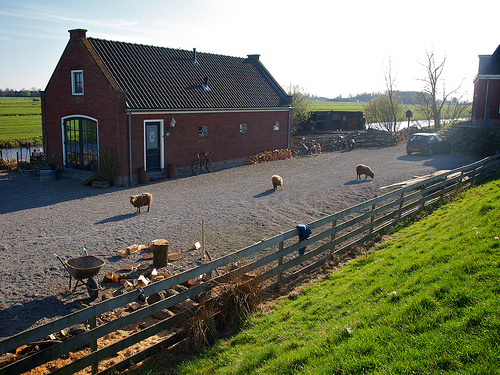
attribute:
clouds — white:
[225, 12, 472, 98]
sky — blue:
[7, 0, 155, 44]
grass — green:
[179, 178, 498, 373]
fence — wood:
[42, 190, 499, 374]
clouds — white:
[298, 13, 430, 75]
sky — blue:
[91, 4, 496, 98]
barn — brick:
[37, 37, 302, 180]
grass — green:
[339, 239, 499, 374]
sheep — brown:
[256, 166, 294, 194]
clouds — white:
[193, 16, 391, 76]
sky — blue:
[2, 2, 493, 104]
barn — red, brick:
[29, 14, 312, 200]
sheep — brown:
[126, 190, 154, 214]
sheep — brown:
[269, 172, 286, 190]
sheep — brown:
[354, 162, 374, 181]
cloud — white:
[0, 12, 190, 33]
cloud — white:
[2, 68, 50, 91]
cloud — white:
[121, 3, 497, 108]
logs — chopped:
[149, 235, 174, 269]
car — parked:
[404, 131, 451, 156]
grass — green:
[126, 174, 498, 374]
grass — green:
[0, 95, 473, 146]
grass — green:
[377, 229, 462, 304]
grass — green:
[1, 94, 39, 137]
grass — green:
[311, 97, 365, 110]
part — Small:
[292, 318, 384, 371]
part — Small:
[454, 186, 493, 241]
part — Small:
[399, 238, 469, 276]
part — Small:
[387, 297, 481, 352]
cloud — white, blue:
[293, 60, 337, 89]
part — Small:
[233, 346, 297, 360]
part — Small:
[265, 312, 321, 352]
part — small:
[345, 288, 402, 333]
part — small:
[386, 246, 418, 278]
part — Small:
[424, 297, 470, 347]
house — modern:
[38, 28, 292, 188]